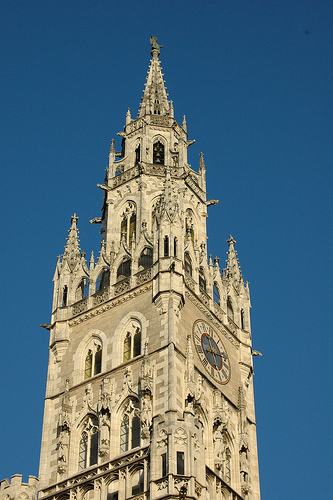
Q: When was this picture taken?
A: During the day.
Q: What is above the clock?
A: A tower.